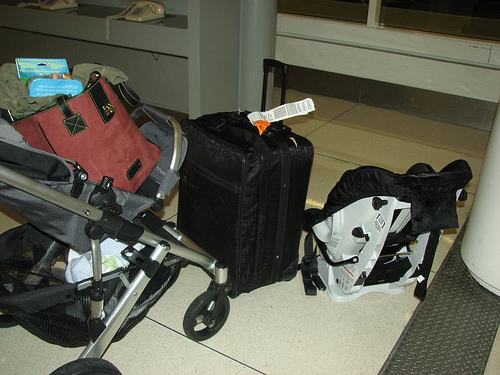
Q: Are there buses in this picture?
A: No, there are no buses.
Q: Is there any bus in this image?
A: No, there are no buses.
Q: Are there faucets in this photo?
A: No, there are no faucets.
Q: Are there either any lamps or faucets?
A: No, there are no faucets or lamps.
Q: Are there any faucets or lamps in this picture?
A: No, there are no faucets or lamps.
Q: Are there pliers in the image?
A: No, there are no pliers.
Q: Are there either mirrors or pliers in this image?
A: No, there are no pliers or mirrors.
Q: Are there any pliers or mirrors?
A: No, there are no pliers or mirrors.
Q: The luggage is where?
A: The luggage is on the floor.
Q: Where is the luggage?
A: The luggage is on the floor.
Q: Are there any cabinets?
A: No, there are no cabinets.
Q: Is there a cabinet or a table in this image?
A: No, there are no cabinets or tables.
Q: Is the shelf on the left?
A: Yes, the shelf is on the left of the image.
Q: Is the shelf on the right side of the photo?
A: No, the shelf is on the left of the image.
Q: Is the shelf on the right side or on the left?
A: The shelf is on the left of the image.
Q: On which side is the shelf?
A: The shelf is on the left of the image.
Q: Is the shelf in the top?
A: Yes, the shelf is in the top of the image.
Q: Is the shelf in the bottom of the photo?
A: No, the shelf is in the top of the image.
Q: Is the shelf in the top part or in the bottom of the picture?
A: The shelf is in the top of the image.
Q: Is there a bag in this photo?
A: Yes, there is a bag.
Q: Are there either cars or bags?
A: Yes, there is a bag.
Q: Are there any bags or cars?
A: Yes, there is a bag.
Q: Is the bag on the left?
A: Yes, the bag is on the left of the image.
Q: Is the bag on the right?
A: No, the bag is on the left of the image.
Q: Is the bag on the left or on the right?
A: The bag is on the left of the image.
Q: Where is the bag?
A: The bag is on the floor.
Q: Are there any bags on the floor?
A: Yes, there is a bag on the floor.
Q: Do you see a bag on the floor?
A: Yes, there is a bag on the floor.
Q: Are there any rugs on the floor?
A: No, there is a bag on the floor.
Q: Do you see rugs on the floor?
A: No, there is a bag on the floor.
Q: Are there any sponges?
A: No, there are no sponges.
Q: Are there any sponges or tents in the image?
A: No, there are no sponges or tents.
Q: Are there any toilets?
A: No, there are no toilets.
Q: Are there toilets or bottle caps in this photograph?
A: No, there are no toilets or bottle caps.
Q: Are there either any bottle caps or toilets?
A: No, there are no toilets or bottle caps.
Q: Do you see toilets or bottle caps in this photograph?
A: No, there are no toilets or bottle caps.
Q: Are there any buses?
A: No, there are no buses.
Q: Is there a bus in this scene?
A: No, there are no buses.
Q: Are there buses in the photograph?
A: No, there are no buses.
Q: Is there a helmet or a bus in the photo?
A: No, there are no buses or helmets.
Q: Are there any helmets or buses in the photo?
A: No, there are no buses or helmets.